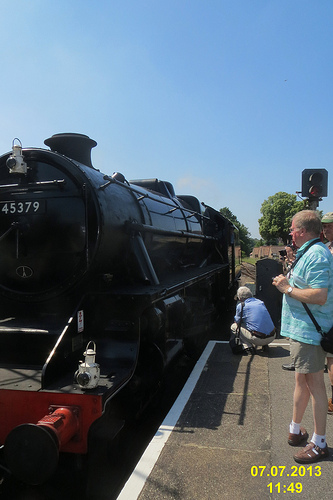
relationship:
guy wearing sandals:
[272, 207, 321, 466] [295, 442, 331, 463]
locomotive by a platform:
[0, 127, 241, 495] [165, 341, 295, 486]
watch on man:
[282, 287, 296, 295] [287, 214, 320, 433]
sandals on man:
[295, 442, 331, 463] [287, 214, 320, 433]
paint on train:
[1, 387, 85, 446] [4, 159, 234, 471]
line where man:
[121, 355, 197, 496] [223, 277, 278, 364]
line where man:
[121, 355, 197, 496] [272, 212, 327, 410]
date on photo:
[247, 467, 323, 476] [7, 134, 323, 493]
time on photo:
[254, 481, 306, 494] [8, 7, 321, 498]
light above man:
[305, 173, 323, 197] [272, 212, 327, 410]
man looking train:
[272, 212, 327, 410] [0, 151, 234, 345]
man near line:
[223, 277, 278, 364] [126, 339, 196, 493]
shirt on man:
[228, 300, 272, 333] [223, 277, 278, 364]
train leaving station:
[4, 159, 234, 471] [13, 151, 321, 480]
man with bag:
[272, 212, 327, 410] [285, 244, 323, 346]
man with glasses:
[272, 212, 327, 410] [284, 218, 300, 239]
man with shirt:
[272, 212, 327, 410] [280, 238, 322, 346]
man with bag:
[272, 212, 327, 410] [286, 266, 322, 348]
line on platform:
[121, 355, 197, 496] [176, 346, 298, 497]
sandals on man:
[295, 442, 331, 463] [285, 207, 322, 462]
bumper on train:
[29, 389, 109, 442] [15, 146, 226, 478]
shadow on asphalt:
[135, 314, 254, 432] [86, 336, 316, 498]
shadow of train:
[135, 314, 254, 432] [1, 129, 241, 470]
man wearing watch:
[272, 212, 327, 410] [280, 279, 296, 298]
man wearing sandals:
[272, 212, 327, 410] [285, 426, 332, 470]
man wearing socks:
[272, 212, 327, 410] [279, 422, 331, 452]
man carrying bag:
[272, 212, 327, 410] [294, 279, 326, 361]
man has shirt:
[223, 277, 278, 364] [229, 299, 289, 336]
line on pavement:
[121, 355, 197, 496] [201, 341, 309, 464]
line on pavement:
[174, 418, 312, 469] [188, 345, 300, 498]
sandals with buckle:
[295, 442, 331, 463] [315, 441, 326, 454]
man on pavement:
[223, 277, 278, 364] [188, 334, 276, 496]